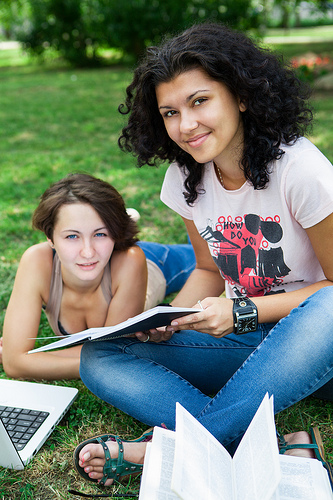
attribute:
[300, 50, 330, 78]
rose — yellow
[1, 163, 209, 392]
person — wearing, holding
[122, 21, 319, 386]
girl — wearing, looking, holding, doing, smile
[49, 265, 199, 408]
book — opened, kept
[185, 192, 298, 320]
shirt — graphic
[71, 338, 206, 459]
jean — blue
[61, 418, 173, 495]
sandal — green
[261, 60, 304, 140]
hair — dark, black, curly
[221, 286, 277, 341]
watch — big, black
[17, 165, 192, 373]
woman — sitting, wearing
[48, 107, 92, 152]
grass — green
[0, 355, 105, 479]
laptop — white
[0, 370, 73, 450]
keyboard — black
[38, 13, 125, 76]
tree — green